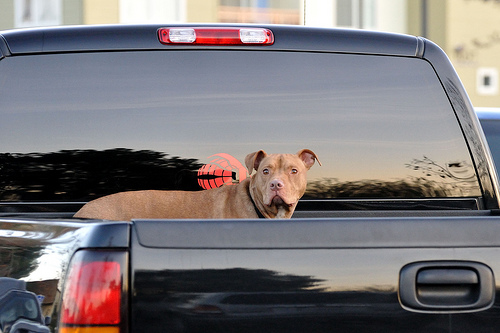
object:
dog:
[72, 150, 321, 220]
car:
[0, 22, 499, 332]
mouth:
[266, 194, 296, 208]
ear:
[245, 149, 268, 174]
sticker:
[198, 151, 246, 192]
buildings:
[1, 1, 499, 113]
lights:
[158, 26, 277, 46]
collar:
[246, 183, 266, 219]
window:
[1, 50, 480, 204]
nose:
[270, 180, 282, 190]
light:
[58, 252, 122, 327]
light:
[57, 325, 119, 333]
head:
[241, 147, 321, 208]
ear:
[298, 149, 322, 169]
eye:
[262, 166, 270, 174]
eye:
[291, 168, 298, 174]